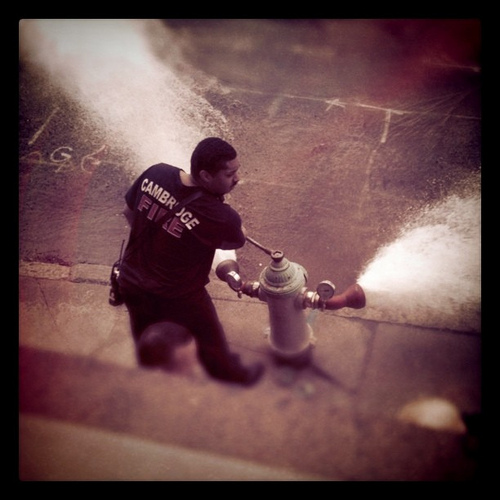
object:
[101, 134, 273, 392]
man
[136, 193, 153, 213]
letters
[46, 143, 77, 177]
letter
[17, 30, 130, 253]
ground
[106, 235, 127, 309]
walkie talkie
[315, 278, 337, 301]
gauge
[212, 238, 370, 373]
fire hydrant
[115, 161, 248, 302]
shirt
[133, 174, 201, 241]
cambridge fire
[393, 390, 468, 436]
head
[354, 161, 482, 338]
water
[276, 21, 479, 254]
street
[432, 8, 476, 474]
left side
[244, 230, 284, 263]
wrench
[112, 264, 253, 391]
pants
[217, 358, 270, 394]
shoes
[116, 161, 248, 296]
back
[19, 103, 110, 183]
drawing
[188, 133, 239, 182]
short hair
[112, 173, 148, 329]
side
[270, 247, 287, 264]
bolt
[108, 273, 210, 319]
hip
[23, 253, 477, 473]
sidewalk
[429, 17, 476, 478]
right side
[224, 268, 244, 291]
guage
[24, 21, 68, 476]
left side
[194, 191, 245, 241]
shoulder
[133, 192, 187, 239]
fire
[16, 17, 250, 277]
water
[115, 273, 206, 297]
belt